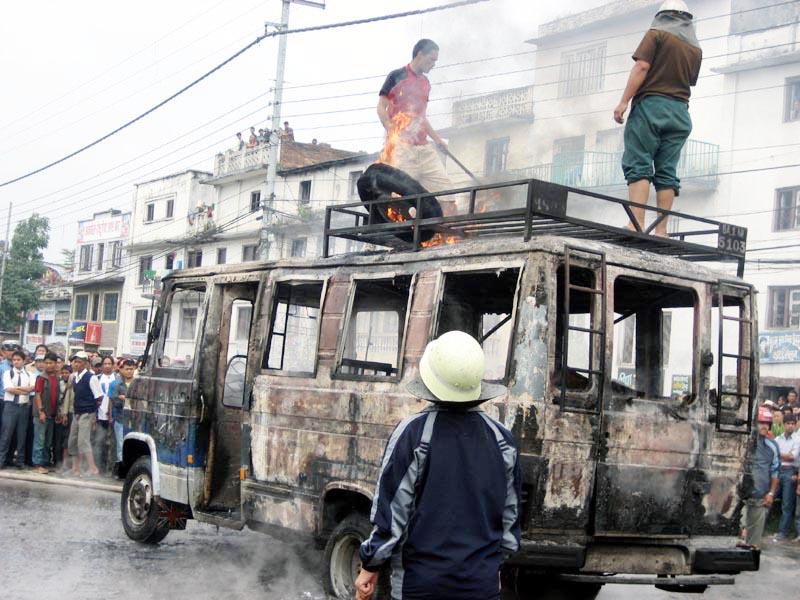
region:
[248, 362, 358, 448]
A person eating a orange.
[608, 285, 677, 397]
window on the car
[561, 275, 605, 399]
window on the car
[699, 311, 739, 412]
window on the car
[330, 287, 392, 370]
window on the car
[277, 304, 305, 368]
window on the car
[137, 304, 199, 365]
window on the car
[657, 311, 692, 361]
window on the car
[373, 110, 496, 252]
Orange fire on top of a van.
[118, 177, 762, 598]
A burning van that has fire on top.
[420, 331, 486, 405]
A thick white helmet.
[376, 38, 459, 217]
Black haired man on top of a van in a red and black shirt.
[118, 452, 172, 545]
Front black tire on a van.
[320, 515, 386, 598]
Rear black and grey van tire.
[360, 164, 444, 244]
Black tire on top of the van.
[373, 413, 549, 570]
Person wearing blue jacket.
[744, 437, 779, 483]
Person wearing gray jacket.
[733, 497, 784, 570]
Person wearing khaki pants.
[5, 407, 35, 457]
Person wearing gray pants.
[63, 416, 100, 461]
Person wearing khaki pants.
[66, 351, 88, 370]
Person wearing hat on head.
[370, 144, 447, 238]
Tire burning on top of van.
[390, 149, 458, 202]
Person wearing khaki shorts.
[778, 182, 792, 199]
a window on the building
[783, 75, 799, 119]
a window on the building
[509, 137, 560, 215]
a window on the building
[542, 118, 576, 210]
a window on the building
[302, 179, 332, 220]
a window on the building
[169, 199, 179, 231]
a window on the building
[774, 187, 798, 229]
building has a window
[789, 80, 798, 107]
building has a window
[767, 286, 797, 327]
building has a window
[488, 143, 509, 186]
building has a window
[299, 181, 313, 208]
building has a window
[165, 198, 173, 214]
building has a window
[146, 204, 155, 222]
building has a window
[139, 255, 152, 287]
building has a window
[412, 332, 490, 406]
The man is wearing a white hat.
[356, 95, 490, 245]
The black tire is on fire.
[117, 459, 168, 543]
The front tire wheel is black in color.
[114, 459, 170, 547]
The front tire is round in shape.